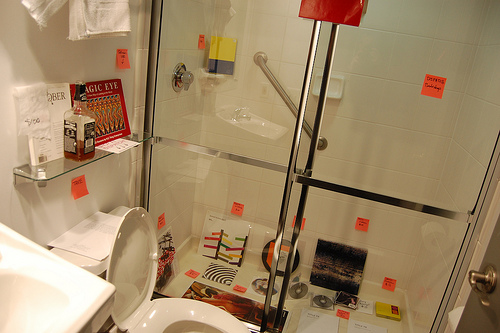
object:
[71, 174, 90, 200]
post-it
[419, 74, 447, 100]
post-it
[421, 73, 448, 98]
red post-it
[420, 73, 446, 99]
neon post-it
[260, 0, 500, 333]
shower door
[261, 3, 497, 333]
glass door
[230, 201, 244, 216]
note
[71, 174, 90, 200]
note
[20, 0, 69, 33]
hand towel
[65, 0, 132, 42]
hand towel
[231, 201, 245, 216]
post-it note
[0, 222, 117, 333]
sink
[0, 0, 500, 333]
wall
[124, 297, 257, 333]
toilet seat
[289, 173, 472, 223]
handle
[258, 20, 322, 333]
metal bar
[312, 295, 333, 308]
cd's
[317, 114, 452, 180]
shower tiles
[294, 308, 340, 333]
paper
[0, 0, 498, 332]
bathroom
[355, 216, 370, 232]
post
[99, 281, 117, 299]
corner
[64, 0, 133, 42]
towel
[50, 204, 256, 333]
toilet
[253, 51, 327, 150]
handle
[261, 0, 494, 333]
door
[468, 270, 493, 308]
handle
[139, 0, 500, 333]
shower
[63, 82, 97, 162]
bottle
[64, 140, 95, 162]
liquor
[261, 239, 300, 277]
record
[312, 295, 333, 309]
cd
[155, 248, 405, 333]
floor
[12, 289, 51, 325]
part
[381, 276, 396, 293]
post it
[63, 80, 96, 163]
glass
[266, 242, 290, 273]
cover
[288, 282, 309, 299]
cd